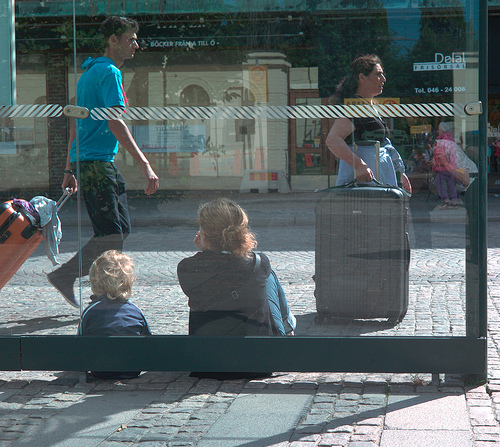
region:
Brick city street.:
[403, 226, 498, 438]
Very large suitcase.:
[300, 180, 446, 320]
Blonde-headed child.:
[75, 242, 150, 367]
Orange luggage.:
[1, 170, 38, 328]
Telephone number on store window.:
[410, 80, 480, 97]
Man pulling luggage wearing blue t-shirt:
[1, 56, 128, 231]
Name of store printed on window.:
[400, 42, 482, 77]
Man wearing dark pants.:
[58, 20, 114, 296]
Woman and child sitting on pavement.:
[80, 187, 308, 372]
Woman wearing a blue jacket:
[175, 196, 302, 336]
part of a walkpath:
[353, 396, 402, 432]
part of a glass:
[260, 244, 317, 303]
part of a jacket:
[228, 296, 250, 315]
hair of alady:
[223, 220, 245, 247]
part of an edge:
[238, 332, 273, 367]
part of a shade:
[287, 400, 329, 430]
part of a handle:
[213, 277, 250, 321]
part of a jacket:
[86, 301, 115, 330]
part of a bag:
[341, 197, 396, 244]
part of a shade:
[326, 406, 355, 437]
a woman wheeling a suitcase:
[315, 55, 413, 192]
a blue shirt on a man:
[58, 53, 138, 158]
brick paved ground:
[277, 372, 390, 441]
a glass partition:
[4, 8, 487, 359]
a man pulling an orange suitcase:
[1, 16, 169, 298]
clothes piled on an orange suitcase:
[9, 191, 67, 261]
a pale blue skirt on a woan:
[336, 136, 402, 197]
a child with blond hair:
[69, 248, 153, 364]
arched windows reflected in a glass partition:
[162, 76, 266, 153]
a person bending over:
[412, 125, 477, 206]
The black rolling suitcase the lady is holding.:
[311, 162, 418, 319]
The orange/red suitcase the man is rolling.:
[4, 195, 49, 300]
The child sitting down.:
[80, 256, 155, 342]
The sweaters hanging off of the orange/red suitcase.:
[19, 185, 69, 265]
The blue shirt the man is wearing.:
[69, 55, 134, 155]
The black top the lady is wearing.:
[333, 96, 390, 142]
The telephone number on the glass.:
[410, 80, 476, 100]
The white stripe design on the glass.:
[4, 95, 471, 127]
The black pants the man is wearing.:
[68, 160, 143, 262]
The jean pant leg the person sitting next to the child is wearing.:
[250, 263, 300, 341]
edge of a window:
[468, 230, 485, 269]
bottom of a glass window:
[368, 348, 415, 377]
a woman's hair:
[218, 213, 225, 219]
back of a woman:
[223, 287, 259, 309]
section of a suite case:
[354, 220, 381, 255]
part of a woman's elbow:
[325, 132, 337, 144]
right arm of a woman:
[342, 130, 344, 160]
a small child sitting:
[90, 270, 129, 332]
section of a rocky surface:
[336, 403, 371, 426]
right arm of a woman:
[126, 126, 158, 176]